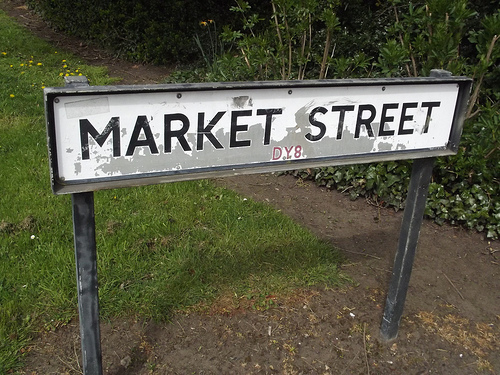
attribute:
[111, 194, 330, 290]
grass — green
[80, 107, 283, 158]
word — capital letter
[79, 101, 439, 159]
market street — black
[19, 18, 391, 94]
flowers — patch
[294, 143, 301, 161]
number — red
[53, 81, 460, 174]
sign — white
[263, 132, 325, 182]
dy8 — red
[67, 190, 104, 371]
bar — metal